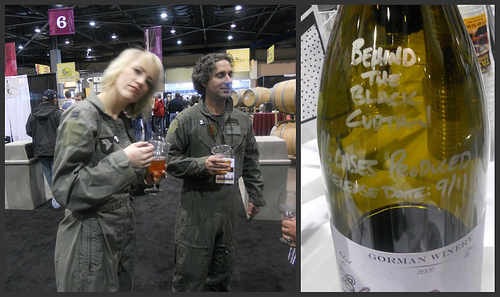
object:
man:
[162, 58, 267, 293]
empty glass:
[276, 188, 297, 220]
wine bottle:
[314, 0, 486, 294]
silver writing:
[350, 37, 417, 70]